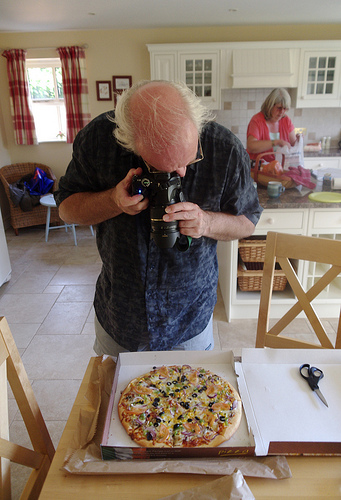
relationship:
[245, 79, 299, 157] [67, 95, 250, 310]
woman behind man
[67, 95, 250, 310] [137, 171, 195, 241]
man holding camera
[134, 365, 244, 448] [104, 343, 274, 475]
pizza in box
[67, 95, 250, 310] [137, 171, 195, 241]
man with camera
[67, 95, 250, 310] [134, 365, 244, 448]
man watching pizza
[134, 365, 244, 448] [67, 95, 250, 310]
pizza near man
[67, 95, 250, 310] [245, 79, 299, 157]
man near woman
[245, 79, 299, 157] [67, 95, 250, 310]
woman near man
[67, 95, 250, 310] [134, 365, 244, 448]
man near pizza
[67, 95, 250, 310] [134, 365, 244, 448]
man with pizza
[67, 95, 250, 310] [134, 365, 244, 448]
man next to pizza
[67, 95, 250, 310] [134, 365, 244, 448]
man looking at pizza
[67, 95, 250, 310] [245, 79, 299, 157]
man with woman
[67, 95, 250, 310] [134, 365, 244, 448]
man has pizza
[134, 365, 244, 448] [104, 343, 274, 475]
pizza inside box